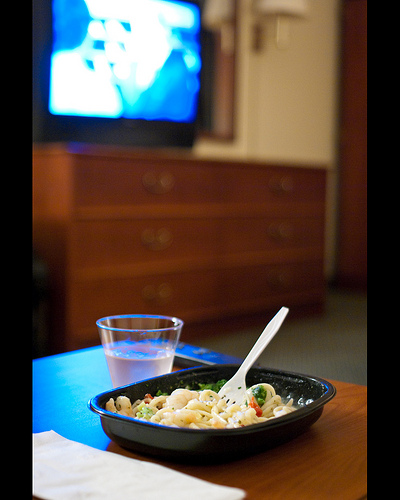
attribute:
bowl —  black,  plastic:
[85, 362, 333, 466]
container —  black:
[85, 362, 335, 462]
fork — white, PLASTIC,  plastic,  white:
[210, 299, 308, 400]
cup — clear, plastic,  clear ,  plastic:
[90, 305, 189, 384]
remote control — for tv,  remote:
[128, 330, 246, 371]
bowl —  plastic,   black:
[97, 358, 350, 450]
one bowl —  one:
[89, 354, 355, 458]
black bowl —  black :
[73, 360, 348, 440]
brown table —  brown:
[33, 317, 367, 499]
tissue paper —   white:
[31, 414, 245, 498]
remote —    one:
[149, 330, 261, 371]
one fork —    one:
[213, 304, 329, 396]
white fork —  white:
[216, 305, 311, 396]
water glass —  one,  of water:
[90, 304, 185, 388]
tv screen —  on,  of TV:
[49, 0, 200, 125]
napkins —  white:
[31, 421, 250, 498]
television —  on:
[49, 1, 196, 124]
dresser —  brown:
[57, 145, 336, 348]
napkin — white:
[32, 420, 246, 495]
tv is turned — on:
[46, 0, 204, 122]